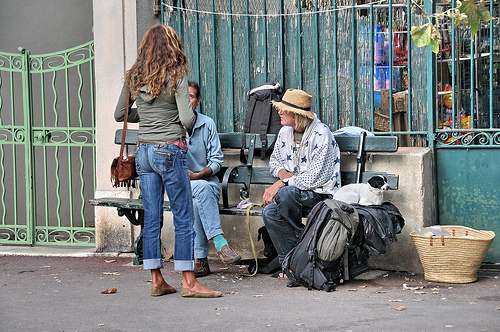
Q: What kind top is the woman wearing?
A: Green hoodie.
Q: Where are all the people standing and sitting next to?
A: Green painted metal.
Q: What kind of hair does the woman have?
A: Long brown hair.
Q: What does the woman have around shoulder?
A: Suede purse.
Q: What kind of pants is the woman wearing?
A: Blue jeans.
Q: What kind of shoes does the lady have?
A: Flats.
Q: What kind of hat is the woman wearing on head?
A: Straw.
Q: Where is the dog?
A: Laying on stack of clothing.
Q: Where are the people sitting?
A: Wooden bench.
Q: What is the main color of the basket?
A: Brown.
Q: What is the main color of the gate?
A: Green.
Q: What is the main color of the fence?
A: Green.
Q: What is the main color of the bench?
A: Green.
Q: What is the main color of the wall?
A: Gray.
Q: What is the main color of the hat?
A: Brown.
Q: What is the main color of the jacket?
A: Black.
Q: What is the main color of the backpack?
A: Black.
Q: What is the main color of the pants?
A: Blue.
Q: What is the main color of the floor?
A: Gray.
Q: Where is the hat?
A: On the woman's head.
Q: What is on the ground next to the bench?
A: A basket.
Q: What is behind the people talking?
A: A fence.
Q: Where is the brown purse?
A: Hanging on the woman's shoulder.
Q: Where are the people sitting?
A: On a bench.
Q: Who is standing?
A: A woman.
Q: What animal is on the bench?
A: A dog.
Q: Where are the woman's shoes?
A: On her feet.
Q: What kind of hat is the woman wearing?
A: A straw hat.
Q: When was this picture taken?
A: During the day.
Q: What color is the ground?
A: Grey.